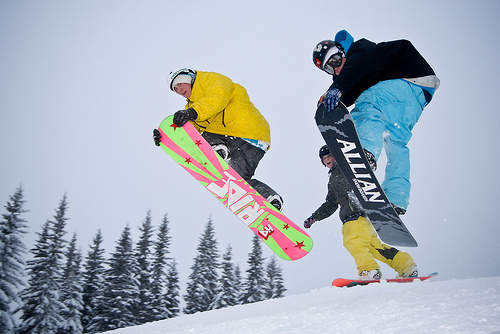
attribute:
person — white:
[152, 66, 283, 210]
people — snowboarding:
[169, 36, 420, 283]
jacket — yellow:
[191, 68, 272, 146]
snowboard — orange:
[331, 262, 443, 289]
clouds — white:
[32, 21, 132, 153]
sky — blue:
[67, 24, 129, 81]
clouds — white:
[67, 52, 118, 125]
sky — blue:
[164, 15, 238, 60]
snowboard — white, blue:
[314, 95, 414, 254]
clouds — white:
[274, 85, 302, 105]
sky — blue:
[1, 1, 498, 293]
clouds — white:
[49, 32, 117, 65]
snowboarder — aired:
[150, 66, 296, 219]